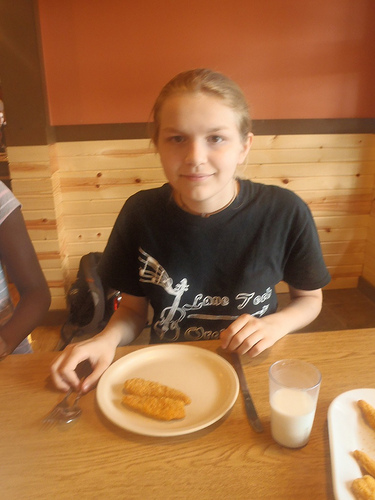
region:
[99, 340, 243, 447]
the plate is tan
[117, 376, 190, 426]
the plate has two chicken strips on it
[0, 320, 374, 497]
the table is wooden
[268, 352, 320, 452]
the cup has milk in it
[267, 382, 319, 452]
the milk is white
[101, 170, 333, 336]
the girl is wearing a shirt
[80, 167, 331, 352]
the girls shirt is black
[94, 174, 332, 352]
the girl is smiling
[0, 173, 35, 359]
the girl to her right is wearing a grey shirt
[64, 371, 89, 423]
the girl is holding her spoon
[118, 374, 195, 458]
Chicken fingers on plate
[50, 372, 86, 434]
Fork and a spoon.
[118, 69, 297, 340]
Girl in black shirt.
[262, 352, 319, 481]
Milk in a glass.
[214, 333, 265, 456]
Knife on the left of plate.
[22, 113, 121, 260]
Wood paneling in the background.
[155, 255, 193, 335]
Violin on the shirt.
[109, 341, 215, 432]
White plate on table.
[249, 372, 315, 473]
Glass on the table.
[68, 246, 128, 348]
Backpack in the back.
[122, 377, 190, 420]
two pieces of chicken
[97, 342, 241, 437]
a white plate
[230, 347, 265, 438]
metal knife to the right of plate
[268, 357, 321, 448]
half full glass of white milk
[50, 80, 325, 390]
girl sitting at table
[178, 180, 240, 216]
necklace around girls neck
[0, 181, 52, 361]
person sitting next to girl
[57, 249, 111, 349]
gray backpack on floor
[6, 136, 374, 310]
wall beneath chair-rail is wood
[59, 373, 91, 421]
girl holding spoon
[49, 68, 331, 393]
A girl wearing a black shirt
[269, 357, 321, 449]
A glass of milk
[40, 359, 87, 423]
A fork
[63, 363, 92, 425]
A spoon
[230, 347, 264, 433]
A knife next to a plate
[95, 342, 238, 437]
A round white plate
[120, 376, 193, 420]
A pair of chicken tenders on a round plate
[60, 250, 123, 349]
A backpack on the floor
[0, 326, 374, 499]
A wooden table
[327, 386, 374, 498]
A white serving platter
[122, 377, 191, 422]
Chicken fingers on plate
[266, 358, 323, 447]
glass half full of milk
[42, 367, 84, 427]
utensils the girl is reaching for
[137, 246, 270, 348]
Wording displayed on girls shirt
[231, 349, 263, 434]
knife resting on table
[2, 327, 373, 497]
wooden table holding food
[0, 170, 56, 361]
girl not in the shot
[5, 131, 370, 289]
wooden wall behind girl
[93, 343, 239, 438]
plate holding chicken fingers